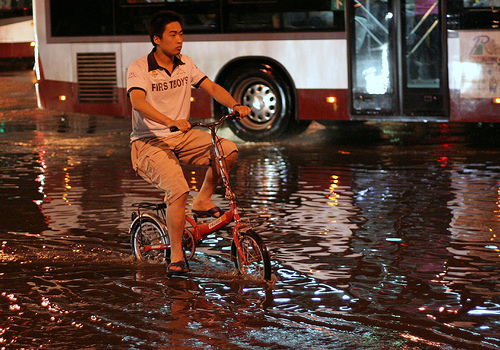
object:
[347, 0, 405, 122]
doors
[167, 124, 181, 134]
handlebars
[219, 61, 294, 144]
tire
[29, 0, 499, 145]
bus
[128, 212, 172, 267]
tire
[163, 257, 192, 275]
flip flops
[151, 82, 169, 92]
lettering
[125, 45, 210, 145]
shirt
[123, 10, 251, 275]
man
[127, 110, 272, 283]
bike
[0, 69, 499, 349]
flooded street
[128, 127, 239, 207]
shorts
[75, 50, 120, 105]
vent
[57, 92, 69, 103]
light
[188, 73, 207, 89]
black trim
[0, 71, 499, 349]
water surface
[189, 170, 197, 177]
lights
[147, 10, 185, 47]
hair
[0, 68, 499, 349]
water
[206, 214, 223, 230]
brand name